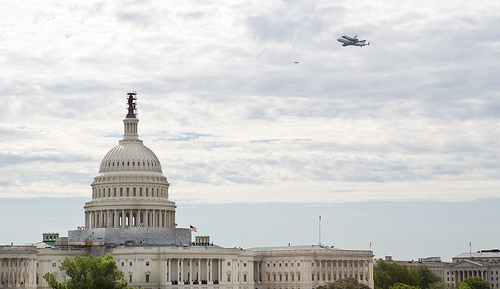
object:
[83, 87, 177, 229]
dome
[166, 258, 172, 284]
column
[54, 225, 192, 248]
construction area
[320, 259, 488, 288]
trees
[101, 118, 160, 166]
roof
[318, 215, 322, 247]
pole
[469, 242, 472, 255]
pole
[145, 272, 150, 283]
window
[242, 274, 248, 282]
window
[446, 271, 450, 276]
window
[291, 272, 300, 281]
window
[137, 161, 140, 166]
window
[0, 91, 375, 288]
large ornatebuilding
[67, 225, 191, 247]
partition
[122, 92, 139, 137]
tower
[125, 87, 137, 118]
antennas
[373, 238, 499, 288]
building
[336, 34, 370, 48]
airplane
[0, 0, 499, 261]
sky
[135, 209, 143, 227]
column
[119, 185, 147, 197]
column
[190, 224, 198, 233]
american flag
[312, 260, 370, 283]
pillars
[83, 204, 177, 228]
pillars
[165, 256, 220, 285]
pillars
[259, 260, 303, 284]
pillars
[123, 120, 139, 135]
pillars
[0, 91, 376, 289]
building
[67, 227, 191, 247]
fence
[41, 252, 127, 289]
tree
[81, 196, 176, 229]
row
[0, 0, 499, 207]
air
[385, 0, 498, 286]
right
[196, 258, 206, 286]
column